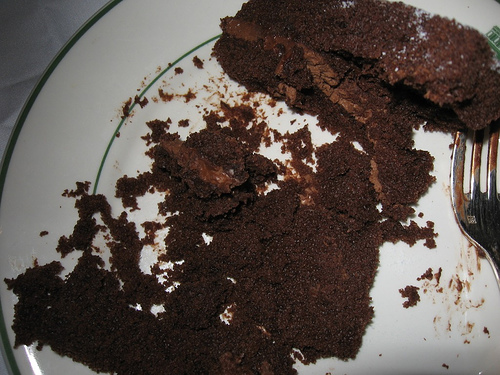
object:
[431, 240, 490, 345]
smear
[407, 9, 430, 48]
powder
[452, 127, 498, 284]
fork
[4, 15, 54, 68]
tablecloth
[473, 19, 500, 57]
design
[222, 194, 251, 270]
chocolate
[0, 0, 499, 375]
cake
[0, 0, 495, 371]
brownie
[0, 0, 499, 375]
plate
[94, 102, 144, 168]
marking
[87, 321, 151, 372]
chocolate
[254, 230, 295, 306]
chocolate